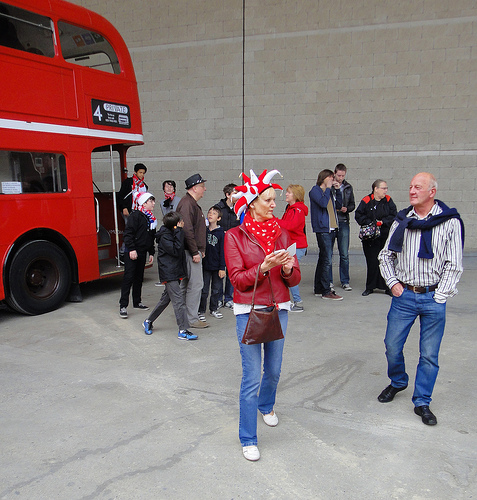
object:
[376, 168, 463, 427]
man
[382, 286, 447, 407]
jeans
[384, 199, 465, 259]
sweater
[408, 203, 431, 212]
neck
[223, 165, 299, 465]
lady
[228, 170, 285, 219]
hat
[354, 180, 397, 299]
person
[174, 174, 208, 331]
grandpa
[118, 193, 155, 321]
person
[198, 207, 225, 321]
kid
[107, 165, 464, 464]
crowd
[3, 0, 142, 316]
bus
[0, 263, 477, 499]
floor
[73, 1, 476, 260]
wall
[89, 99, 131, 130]
signage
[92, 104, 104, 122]
number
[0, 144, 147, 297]
deck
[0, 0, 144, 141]
deck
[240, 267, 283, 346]
purse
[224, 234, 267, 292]
arm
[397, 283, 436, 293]
belt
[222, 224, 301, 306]
jacket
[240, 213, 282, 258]
scarf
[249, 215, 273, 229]
neck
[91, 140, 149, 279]
door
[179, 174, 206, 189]
hat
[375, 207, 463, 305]
shirt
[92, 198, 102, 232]
railing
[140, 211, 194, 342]
boy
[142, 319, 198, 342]
sneakers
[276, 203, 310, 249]
sweatshirt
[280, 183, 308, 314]
lady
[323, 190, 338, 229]
scarf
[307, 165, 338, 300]
guy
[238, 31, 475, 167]
tiles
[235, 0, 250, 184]
lines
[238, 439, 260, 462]
foot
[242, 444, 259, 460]
sneaker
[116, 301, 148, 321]
sneakers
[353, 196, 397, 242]
jacket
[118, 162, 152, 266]
passenger